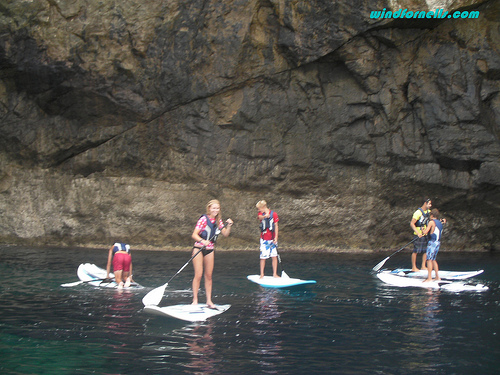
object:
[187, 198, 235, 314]
woman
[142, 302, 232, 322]
board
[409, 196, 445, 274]
man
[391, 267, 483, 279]
board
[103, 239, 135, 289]
person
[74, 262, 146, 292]
board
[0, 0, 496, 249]
cliff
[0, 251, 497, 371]
water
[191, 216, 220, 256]
swimsuit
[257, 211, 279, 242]
shirt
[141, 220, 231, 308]
oar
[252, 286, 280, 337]
reflection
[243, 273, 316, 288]
board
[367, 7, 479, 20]
website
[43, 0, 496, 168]
crack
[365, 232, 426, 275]
paddle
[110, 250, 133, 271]
shorts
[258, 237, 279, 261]
shorts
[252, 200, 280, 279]
boy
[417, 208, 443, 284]
person